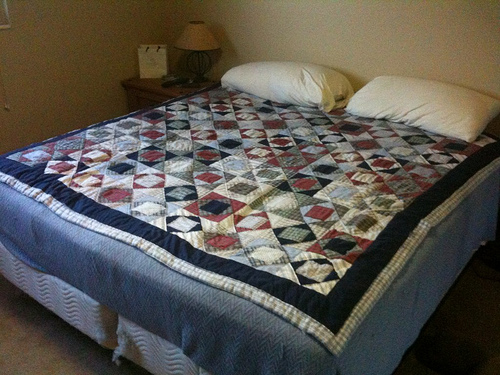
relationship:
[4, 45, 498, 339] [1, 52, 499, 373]
quilt on bed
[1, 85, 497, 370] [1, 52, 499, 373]
blanket on bed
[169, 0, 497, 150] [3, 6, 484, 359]
tan wall of room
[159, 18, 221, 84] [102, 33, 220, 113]
lamp of nightstand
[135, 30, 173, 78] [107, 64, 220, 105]
bag sitting nightstand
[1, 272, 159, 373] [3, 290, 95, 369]
carpet of ground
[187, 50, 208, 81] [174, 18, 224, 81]
base of lamp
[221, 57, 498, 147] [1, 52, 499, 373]
pillows on bed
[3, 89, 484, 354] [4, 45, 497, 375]
bed covered quilt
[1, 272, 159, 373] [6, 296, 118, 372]
carpet of floor